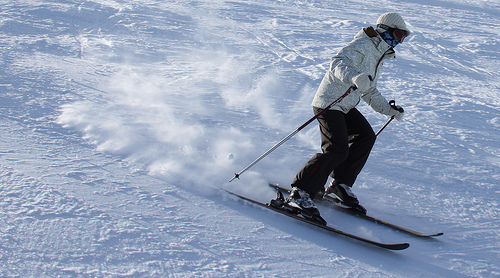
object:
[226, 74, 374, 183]
pole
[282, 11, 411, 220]
man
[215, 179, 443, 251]
skis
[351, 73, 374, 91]
glove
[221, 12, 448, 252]
man skies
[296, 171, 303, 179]
wrinkle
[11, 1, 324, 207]
tracks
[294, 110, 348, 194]
leg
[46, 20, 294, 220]
snow dust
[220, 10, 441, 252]
ski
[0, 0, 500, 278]
snow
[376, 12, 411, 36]
hat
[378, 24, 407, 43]
goggles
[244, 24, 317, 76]
marks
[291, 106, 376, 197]
pants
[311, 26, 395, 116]
jacket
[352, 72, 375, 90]
hand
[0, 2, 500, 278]
hillside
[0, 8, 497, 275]
hill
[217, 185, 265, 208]
end